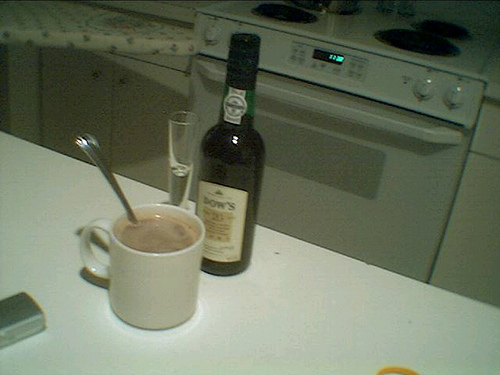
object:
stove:
[196, 0, 486, 284]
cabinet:
[0, 0, 497, 308]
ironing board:
[0, 1, 201, 57]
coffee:
[78, 204, 206, 331]